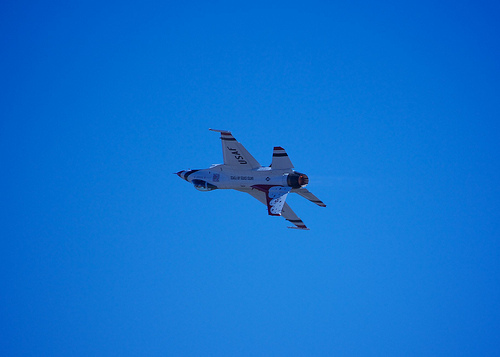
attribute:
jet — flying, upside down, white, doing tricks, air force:
[161, 102, 335, 252]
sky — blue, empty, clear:
[184, 27, 271, 74]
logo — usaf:
[221, 137, 247, 168]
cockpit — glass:
[192, 172, 217, 198]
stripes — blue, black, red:
[206, 114, 247, 150]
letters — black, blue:
[227, 143, 240, 155]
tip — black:
[219, 128, 233, 139]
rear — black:
[265, 152, 316, 200]